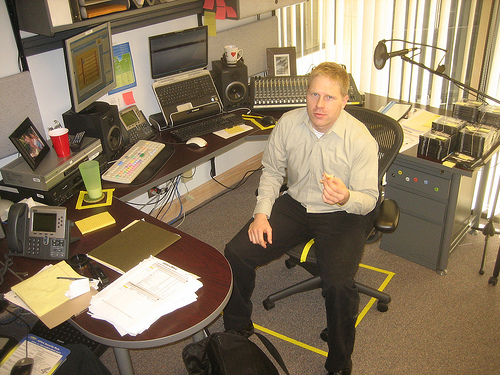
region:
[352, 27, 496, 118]
Black microphone in the air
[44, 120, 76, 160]
Red plastic cup with white inside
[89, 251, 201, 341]
Pile of white papers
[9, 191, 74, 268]
Gray and silver telephone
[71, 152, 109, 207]
Light green cup with white liquid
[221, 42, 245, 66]
White mug with red heart on it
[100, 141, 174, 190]
White keyboard with colored letters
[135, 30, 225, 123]
Gray and black open laptop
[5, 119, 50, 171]
Photo in black frame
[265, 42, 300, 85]
Photo in brown frame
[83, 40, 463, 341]
man surrounded by desk on three sides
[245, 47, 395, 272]
man with food in his hand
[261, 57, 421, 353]
yellow lines underneath office chair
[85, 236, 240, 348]
papers at the end of a curved table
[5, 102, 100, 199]
photograph, cup and remote controls on top of electronic device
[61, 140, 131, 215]
cup in the middle of square border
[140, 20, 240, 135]
laptop lifted up and open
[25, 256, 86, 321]
pen on top of yellow pad of paper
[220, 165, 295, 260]
hand resting on thigh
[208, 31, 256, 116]
mug on top of a speaker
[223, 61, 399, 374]
man sitting in chair eating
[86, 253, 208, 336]
pile of white papers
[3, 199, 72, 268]
gray phone with cord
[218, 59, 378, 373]
man in black pants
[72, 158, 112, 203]
green cup with drink in it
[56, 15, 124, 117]
computer monitor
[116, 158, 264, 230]
cords hanging below desk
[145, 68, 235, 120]
propped up black keyboard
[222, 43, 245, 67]
white mug with red heart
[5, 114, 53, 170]
photo in black frame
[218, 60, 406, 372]
man sitting in office chair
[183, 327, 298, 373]
black carrying case on floor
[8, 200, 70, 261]
gray phone on desk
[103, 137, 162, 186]
white computer keyboard on desk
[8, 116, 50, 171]
framed photo on equipment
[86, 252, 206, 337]
stack of papers on desk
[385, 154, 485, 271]
gray file cabinet near window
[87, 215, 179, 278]
hanging file folder on desk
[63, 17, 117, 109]
computer monitor on speaker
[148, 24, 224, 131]
laptop computer on stand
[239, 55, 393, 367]
Middle aged man sitting in a chair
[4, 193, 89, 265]
Black and grey office phone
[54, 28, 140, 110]
Computer screen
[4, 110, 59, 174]
Picture with a black frame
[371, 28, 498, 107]
Black microphone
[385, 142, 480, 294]
Grey filing cabinet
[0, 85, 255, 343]
Office desk covered in stuff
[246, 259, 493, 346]
Yellow tape outlining an area on the floor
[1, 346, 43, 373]
Black and grey computer mouse